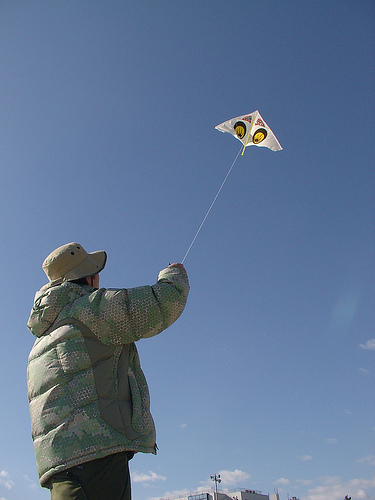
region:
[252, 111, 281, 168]
The left side of the white kite.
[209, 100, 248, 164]
The right side of the white kite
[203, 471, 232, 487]
The top of a speaker pole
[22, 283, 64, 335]
The man's light green hood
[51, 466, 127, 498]
The man's olive green trousers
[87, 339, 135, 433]
The dark grey parts of the man's jacket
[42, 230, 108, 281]
The Man's Beige Top Hat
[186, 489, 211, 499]
A portion of the glass mirrors on the building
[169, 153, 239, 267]
The white string of the kite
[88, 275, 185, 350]
The puffy arm of the man's jacket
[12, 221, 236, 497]
a person flying a kite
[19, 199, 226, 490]
a person wearing a hat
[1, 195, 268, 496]
a person wearing a jacket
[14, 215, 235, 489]
a person wearing a puffy jacket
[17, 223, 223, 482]
a person wearing a silver jacket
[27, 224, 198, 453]
a person wearing a silver poofy jacket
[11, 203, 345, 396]
a person holding a string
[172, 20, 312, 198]
a kite in the air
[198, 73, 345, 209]
a kite in the sky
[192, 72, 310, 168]
a kite flying in the air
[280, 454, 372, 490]
White clouds in the sky.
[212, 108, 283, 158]
A white kite in the sky.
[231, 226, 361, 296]
A crystal blue sky on a clear day.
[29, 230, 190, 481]
A man wearing a puffy gray jacket.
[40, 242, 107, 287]
A beige fishing hat with holes in it.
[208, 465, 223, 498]
A large street lamp with three lights.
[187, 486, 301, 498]
The tops of several buildings.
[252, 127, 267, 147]
A yellow and black design on a white kite.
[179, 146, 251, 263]
White string holding a triangle shaped kite.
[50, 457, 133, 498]
Green wrinkled pants bunched up.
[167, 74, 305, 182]
Kite in the sky.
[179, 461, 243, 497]
Building in the background.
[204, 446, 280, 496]
White clouds in the sky.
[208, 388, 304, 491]
Blue sky with white clouds.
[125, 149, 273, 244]
String on the kite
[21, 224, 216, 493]
Man with a kite.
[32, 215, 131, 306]
Man with a hat.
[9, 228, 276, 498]
Man in a puffy coat.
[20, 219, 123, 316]
Fishing hat on the man.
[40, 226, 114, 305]
Grommets on the hat.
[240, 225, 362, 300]
large patch of blue sky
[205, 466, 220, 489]
speakers on a pole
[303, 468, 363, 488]
low lying clouds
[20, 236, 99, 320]
man's hat and hood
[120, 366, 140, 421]
pocket of a jacket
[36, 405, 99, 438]
camouflage pattern on the jacket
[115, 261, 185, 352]
man's arm held up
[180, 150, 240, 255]
long white kite string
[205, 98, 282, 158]
kite with two yellow eyes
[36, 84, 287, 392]
man flies his kite high in the cloudless sky